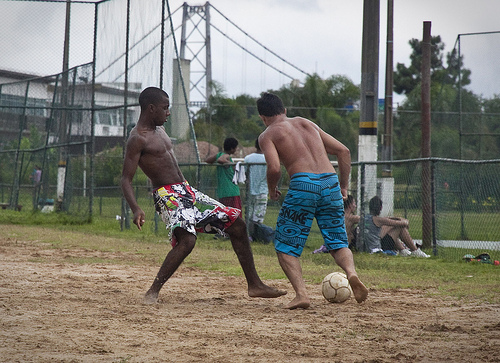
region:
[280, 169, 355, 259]
the short is blue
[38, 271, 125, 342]
the ground is brown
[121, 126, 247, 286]
the man is shirtless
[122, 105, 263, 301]
the man is black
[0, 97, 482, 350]
the game is soccer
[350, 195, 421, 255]
they are sitted down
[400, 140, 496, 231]
the fence is chained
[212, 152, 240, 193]
the shirt is blue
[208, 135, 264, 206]
the boys are standing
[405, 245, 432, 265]
the shoes are white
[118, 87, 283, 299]
black boy in colorful shorts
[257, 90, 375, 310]
boy in long blue shorts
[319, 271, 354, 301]
white soccer ball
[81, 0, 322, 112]
grey suspension bridge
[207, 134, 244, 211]
boy in green t-shirt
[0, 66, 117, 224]
green chain-link fence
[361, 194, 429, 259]
girl with ponytail and white sneakers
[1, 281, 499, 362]
dirt on playing field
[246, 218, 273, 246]
blue backpack on ground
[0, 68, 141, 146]
white and brown building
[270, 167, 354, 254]
turquoise and black swim trunks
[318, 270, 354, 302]
dirty white soccer ball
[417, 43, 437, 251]
rusty metal utility pole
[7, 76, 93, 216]
black chain link fence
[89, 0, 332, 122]
top of suspension bridge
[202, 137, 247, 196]
boy in green shirt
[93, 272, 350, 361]
footprints in the dirt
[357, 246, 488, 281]
green grass next to fence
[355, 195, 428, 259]
girl sitting with her back on fence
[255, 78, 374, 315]
boy kicking soccer ball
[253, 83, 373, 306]
Man wearing blue shorts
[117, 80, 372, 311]
Men going after white soccer ball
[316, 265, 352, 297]
Soccer ball is dirty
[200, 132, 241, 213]
Man in green tank leaning against fence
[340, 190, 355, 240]
Shirtless man sitting against fence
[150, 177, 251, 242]
Shorts are long and colorful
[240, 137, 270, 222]
Man in light blue shirt standing next to man in green shirt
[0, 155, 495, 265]
Fence is black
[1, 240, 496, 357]
Dirt is muddy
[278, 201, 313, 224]
Snake logo on blue shorts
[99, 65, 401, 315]
two young men playing with a soccer ball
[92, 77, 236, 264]
a man wearing colorful shorts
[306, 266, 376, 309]
a white soccer ball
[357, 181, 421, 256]
a person sitting on the ground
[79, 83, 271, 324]
a man lifting his foot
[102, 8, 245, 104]
a tall bridge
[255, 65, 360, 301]
a man wearing blue and black shorts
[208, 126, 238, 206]
a man wearing a green shirt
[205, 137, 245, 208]
a man wearing red shorts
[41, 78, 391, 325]
two people kicking a soccer ball